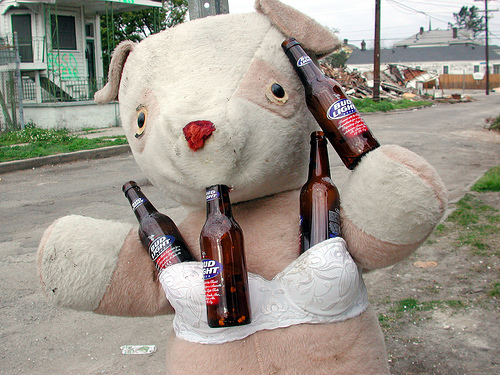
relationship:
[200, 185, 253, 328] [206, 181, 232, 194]
bottle in mouth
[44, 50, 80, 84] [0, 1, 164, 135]
graffiti on house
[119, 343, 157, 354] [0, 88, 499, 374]
litter on ground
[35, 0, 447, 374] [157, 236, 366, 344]
animal has bra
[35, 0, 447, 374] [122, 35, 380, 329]
animal has bottles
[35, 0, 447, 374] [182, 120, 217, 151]
animal has nose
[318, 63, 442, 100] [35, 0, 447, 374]
junk behind animal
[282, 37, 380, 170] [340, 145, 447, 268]
bottle on hand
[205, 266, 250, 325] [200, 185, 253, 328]
stuff inside bottle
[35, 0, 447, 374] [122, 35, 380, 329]
animal holding bottles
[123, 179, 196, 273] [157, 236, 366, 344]
bottle in bra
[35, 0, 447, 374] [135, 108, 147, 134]
animal has eye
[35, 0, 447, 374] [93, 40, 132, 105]
animal has ear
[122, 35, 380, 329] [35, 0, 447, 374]
bottles on animal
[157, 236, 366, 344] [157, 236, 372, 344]
bra has pattern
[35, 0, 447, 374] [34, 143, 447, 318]
animal has paws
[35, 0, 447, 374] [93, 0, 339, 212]
animal has head